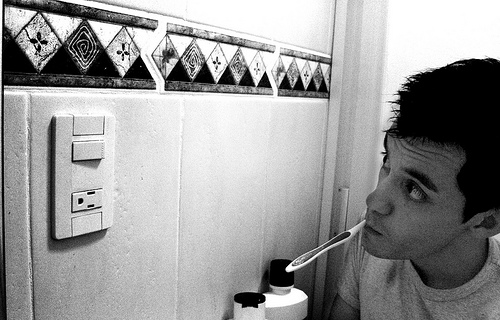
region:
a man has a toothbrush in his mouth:
[278, 55, 498, 274]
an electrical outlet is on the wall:
[48, 111, 116, 241]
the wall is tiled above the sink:
[6, 89, 328, 317]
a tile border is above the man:
[3, 0, 335, 98]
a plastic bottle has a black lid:
[266, 257, 307, 319]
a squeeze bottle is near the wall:
[233, 290, 268, 318]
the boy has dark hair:
[388, 55, 499, 223]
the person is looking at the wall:
[180, 60, 498, 265]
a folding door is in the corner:
[318, 2, 386, 319]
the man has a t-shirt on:
[334, 203, 499, 317]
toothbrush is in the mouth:
[270, 208, 406, 319]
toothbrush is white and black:
[284, 219, 371, 276]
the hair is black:
[397, 78, 491, 133]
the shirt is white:
[348, 266, 483, 318]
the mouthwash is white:
[258, 251, 316, 315]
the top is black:
[259, 259, 306, 289]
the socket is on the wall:
[41, 111, 124, 249]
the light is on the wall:
[185, 127, 300, 204]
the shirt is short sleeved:
[347, 256, 498, 318]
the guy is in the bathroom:
[17, 10, 499, 312]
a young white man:
[248, 54, 494, 306]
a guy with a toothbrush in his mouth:
[256, 35, 498, 318]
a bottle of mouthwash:
[264, 245, 318, 317]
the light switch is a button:
[39, 82, 158, 267]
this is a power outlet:
[61, 182, 153, 212]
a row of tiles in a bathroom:
[16, 13, 353, 105]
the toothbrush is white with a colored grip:
[256, 216, 375, 285]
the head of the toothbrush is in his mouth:
[273, 209, 421, 286]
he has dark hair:
[385, 51, 499, 238]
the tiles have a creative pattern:
[13, 0, 348, 110]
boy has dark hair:
[367, 55, 494, 214]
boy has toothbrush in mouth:
[240, 214, 389, 286]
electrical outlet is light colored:
[52, 117, 129, 252]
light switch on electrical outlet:
[44, 108, 113, 181]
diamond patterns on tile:
[14, 27, 306, 77]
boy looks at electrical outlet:
[358, 9, 499, 310]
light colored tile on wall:
[158, 129, 278, 238]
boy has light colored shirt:
[358, 231, 475, 318]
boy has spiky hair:
[380, 60, 499, 242]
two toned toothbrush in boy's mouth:
[290, 214, 377, 270]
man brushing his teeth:
[252, 46, 498, 308]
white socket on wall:
[57, 110, 115, 236]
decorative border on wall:
[7, 2, 334, 91]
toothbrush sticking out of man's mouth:
[271, 212, 379, 268]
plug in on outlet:
[65, 186, 101, 211]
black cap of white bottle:
[258, 250, 293, 289]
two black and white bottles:
[221, 255, 303, 315]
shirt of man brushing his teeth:
[337, 229, 495, 319]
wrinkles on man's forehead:
[382, 128, 457, 173]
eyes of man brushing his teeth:
[376, 150, 424, 200]